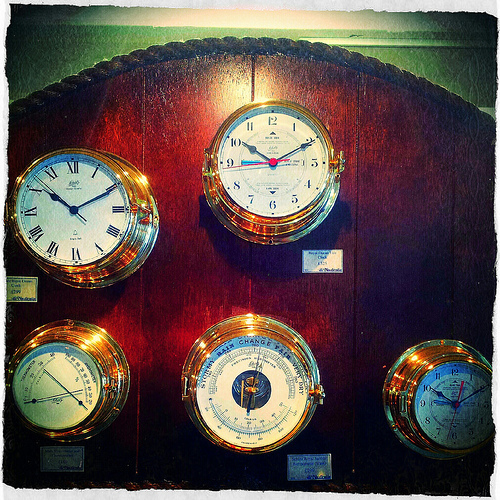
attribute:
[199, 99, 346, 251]
clock — ciircular, analog, framed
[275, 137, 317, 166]
hand — black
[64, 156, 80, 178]
roman numeral — number 12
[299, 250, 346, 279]
card — white, small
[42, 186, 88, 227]
hour hand — black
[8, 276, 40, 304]
sign — small, white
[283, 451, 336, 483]
card — small, white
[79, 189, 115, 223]
minute hand — black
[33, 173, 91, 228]
second hand — black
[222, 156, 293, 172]
second hand — red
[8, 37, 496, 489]
wood — carved, curved, dark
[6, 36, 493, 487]
panel — wood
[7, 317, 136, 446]
frame — brass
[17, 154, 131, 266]
face — white